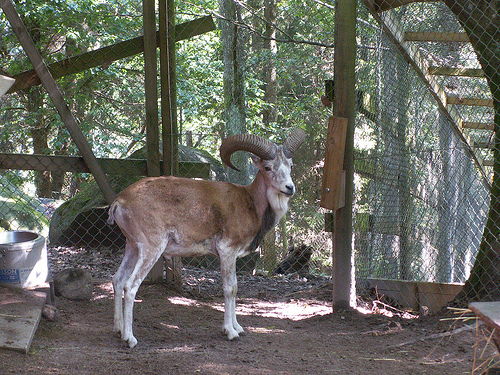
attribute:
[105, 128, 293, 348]
goat — standing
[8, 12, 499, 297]
fence — tall, meshed, gray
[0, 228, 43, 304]
bucket — white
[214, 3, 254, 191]
tree — tall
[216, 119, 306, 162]
horns — big, curved, sharp, grey, bent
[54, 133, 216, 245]
rock — big, green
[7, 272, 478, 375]
dirt — brown, rough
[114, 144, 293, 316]
animal — brown, standing, enclosed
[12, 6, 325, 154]
leaves — green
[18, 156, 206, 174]
wood — brown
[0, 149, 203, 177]
boards — long, wooden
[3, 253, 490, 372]
ground — brown, dirty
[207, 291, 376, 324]
reflection — light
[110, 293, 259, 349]
feet — white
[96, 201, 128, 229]
tail — short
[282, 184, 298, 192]
nose — black